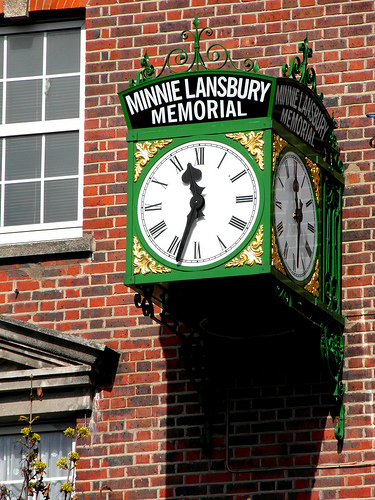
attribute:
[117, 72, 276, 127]
lettering — white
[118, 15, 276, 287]
green — decorative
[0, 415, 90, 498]
weeds — yellow, pompom-like, tall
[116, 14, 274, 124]
sign — memorial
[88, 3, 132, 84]
wall — brick, red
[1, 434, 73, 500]
curtains — white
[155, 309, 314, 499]
shadow — huge, cast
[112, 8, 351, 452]
frame — green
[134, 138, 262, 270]
face — white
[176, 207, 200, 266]
arm — long, black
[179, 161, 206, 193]
arm — short, black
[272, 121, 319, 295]
watch — white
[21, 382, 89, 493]
element — decorative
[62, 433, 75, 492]
flowers — yellow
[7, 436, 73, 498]
curtains — white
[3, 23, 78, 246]
blinds — venetian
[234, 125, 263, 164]
leaves — gold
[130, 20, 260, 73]
curliques — iron